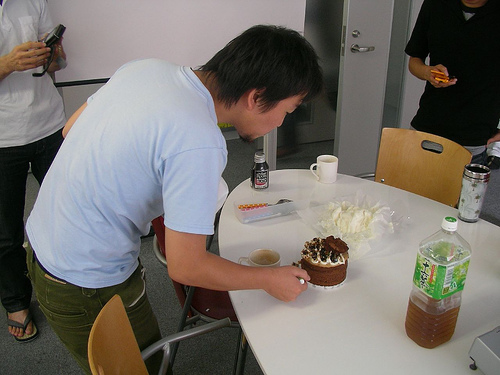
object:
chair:
[87, 294, 233, 374]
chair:
[374, 127, 472, 208]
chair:
[151, 216, 248, 375]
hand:
[264, 265, 311, 303]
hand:
[428, 64, 457, 88]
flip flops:
[6, 310, 40, 343]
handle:
[310, 163, 320, 180]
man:
[22, 24, 324, 375]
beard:
[237, 133, 258, 145]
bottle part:
[400, 274, 460, 350]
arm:
[162, 147, 268, 290]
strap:
[32, 47, 57, 78]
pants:
[22, 235, 169, 375]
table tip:
[271, 168, 301, 178]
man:
[0, 0, 69, 342]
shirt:
[25, 58, 229, 289]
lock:
[352, 30, 360, 39]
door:
[334, 0, 396, 179]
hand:
[487, 134, 500, 148]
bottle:
[405, 216, 471, 349]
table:
[218, 168, 499, 375]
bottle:
[250, 151, 269, 189]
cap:
[442, 216, 458, 229]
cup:
[310, 155, 339, 184]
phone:
[431, 69, 455, 83]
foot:
[8, 308, 33, 336]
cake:
[292, 235, 348, 286]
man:
[402, 0, 499, 160]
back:
[374, 125, 470, 205]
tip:
[254, 151, 266, 163]